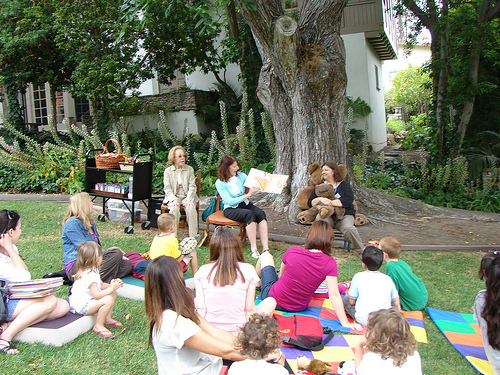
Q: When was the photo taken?
A: During the day.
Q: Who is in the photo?
A: People.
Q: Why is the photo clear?
A: Its during the day.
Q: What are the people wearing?
A: Clothes.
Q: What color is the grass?
A: Green.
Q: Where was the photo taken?
A: On a lawn.